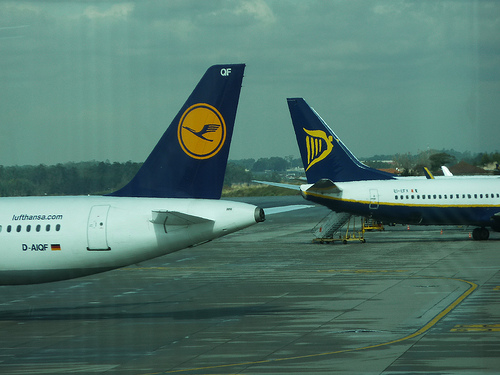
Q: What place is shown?
A: It is a runway.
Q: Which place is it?
A: It is a runway.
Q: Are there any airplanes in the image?
A: Yes, there is an airplane.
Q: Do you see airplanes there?
A: Yes, there is an airplane.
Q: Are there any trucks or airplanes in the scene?
A: Yes, there is an airplane.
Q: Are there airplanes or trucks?
A: Yes, there is an airplane.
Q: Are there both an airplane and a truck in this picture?
A: No, there is an airplane but no trucks.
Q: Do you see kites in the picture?
A: No, there are no kites.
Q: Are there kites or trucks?
A: No, there are no kites or trucks.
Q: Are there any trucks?
A: No, there are no trucks.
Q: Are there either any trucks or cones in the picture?
A: No, there are no trucks or cones.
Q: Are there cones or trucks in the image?
A: No, there are no trucks or cones.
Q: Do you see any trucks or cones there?
A: No, there are no trucks or cones.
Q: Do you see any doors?
A: Yes, there is a door.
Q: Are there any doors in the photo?
A: Yes, there is a door.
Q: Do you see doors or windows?
A: Yes, there is a door.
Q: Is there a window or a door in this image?
A: Yes, there is a door.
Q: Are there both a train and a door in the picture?
A: No, there is a door but no trains.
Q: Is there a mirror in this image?
A: No, there are no mirrors.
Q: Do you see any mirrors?
A: No, there are no mirrors.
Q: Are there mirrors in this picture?
A: No, there are no mirrors.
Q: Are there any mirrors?
A: No, there are no mirrors.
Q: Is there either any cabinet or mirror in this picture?
A: No, there are no mirrors or cabinets.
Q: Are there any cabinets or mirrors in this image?
A: No, there are no mirrors or cabinets.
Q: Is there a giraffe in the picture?
A: No, there are no giraffes.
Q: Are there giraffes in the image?
A: No, there are no giraffes.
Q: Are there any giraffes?
A: No, there are no giraffes.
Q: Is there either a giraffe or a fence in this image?
A: No, there are no giraffes or fences.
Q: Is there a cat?
A: No, there are no cats.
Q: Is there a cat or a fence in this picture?
A: No, there are no cats or fences.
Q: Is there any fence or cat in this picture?
A: No, there are no cats or fences.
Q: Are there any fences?
A: No, there are no fences.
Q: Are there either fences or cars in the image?
A: No, there are no fences or cars.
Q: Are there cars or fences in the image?
A: No, there are no fences or cars.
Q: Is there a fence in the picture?
A: No, there are no fences.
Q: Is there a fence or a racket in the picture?
A: No, there are no fences or rackets.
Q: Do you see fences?
A: No, there are no fences.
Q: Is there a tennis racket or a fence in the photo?
A: No, there are no fences or rackets.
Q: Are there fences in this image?
A: No, there are no fences.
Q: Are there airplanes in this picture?
A: Yes, there is an airplane.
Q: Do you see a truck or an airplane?
A: Yes, there is an airplane.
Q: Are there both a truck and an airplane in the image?
A: No, there is an airplane but no trucks.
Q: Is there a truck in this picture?
A: No, there are no trucks.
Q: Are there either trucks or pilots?
A: No, there are no trucks or pilots.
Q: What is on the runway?
A: The airplane is on the runway.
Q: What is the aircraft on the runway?
A: The aircraft is an airplane.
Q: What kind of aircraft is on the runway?
A: The aircraft is an airplane.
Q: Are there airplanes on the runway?
A: Yes, there is an airplane on the runway.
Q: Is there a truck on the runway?
A: No, there is an airplane on the runway.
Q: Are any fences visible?
A: No, there are no fences.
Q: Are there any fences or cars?
A: No, there are no fences or cars.